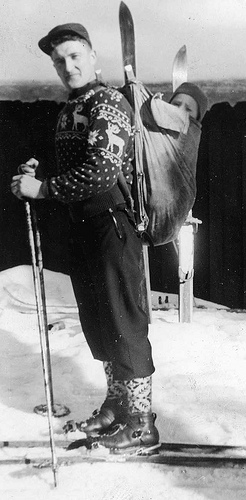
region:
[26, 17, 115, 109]
a man wearing a hat.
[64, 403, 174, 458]
a left foot shoe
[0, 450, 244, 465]
a ski in the snow.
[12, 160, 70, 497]
a ski pole.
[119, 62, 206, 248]
a kid in a nap sack.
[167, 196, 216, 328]
a metal object in the snow.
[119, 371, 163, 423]
a thermal sock.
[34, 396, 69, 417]
a round object in the snow.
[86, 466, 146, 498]
a section of white snow.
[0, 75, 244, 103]
snow covered land.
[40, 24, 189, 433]
a man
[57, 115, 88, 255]
a man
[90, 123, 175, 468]
a man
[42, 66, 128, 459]
a man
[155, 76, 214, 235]
child being carried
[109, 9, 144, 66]
skiis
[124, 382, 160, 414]
man wearing socks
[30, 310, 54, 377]
ski poles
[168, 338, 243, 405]
the white snow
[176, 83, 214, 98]
child wearing a hat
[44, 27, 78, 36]
man wearing a hat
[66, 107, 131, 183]
man wearing a sweater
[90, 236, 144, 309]
man wearing pants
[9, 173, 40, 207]
man holding ski poles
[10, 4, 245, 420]
the photograph is black and white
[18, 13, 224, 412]
the man is skiing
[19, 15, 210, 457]
the man wearing a cap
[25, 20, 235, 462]
a man carrying a child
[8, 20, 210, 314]
the man wearing a sweater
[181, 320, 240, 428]
snow on the ground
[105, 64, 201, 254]
the child in a napsack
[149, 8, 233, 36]
the sun is shining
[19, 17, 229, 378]
the man holding ski poles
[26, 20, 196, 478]
the man wearing skis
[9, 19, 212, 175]
black and white photo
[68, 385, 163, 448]
feet of the person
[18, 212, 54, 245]
ski poles in front of man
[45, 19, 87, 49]
hat on man's head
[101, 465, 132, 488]
snow next to person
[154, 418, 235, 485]
skis in the snow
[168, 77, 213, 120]
kid in a sack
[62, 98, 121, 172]
outfit on the man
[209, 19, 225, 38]
sky in the background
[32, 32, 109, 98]
man looking at the camera